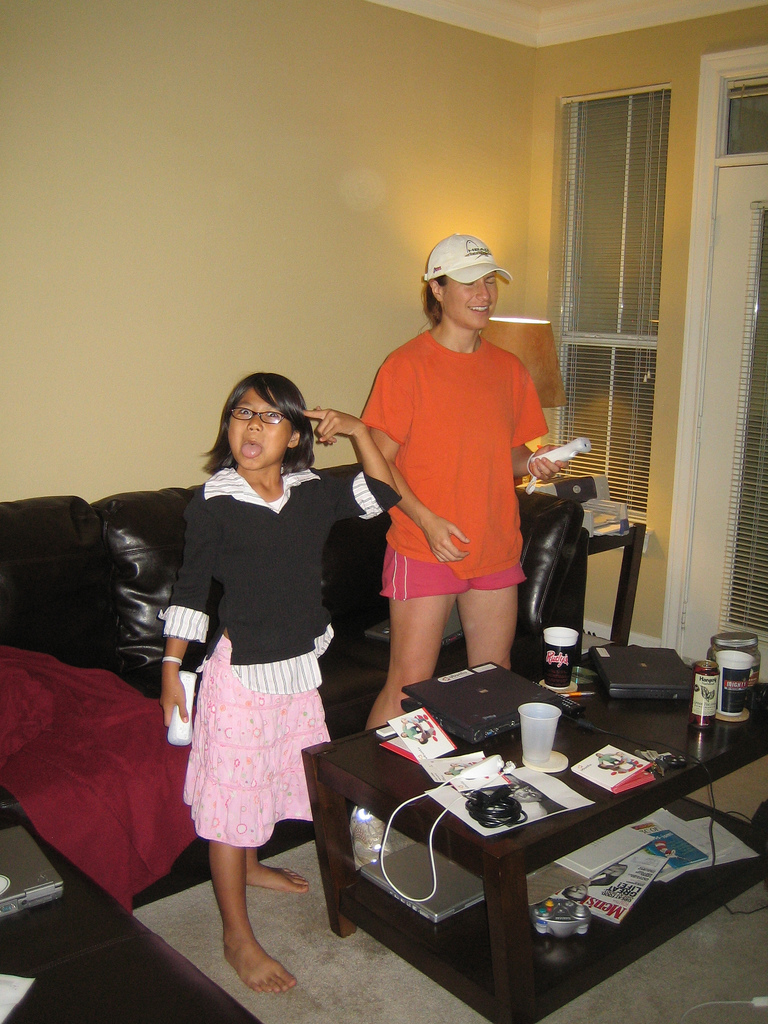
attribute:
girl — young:
[169, 344, 360, 547]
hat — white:
[416, 215, 531, 302]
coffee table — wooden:
[271, 668, 758, 979]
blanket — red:
[6, 645, 190, 853]